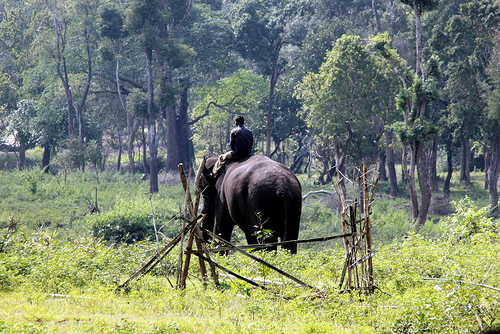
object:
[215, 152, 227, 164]
knee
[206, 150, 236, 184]
leg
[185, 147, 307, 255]
elephant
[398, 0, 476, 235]
trees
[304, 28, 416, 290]
trees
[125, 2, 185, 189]
trees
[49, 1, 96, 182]
trees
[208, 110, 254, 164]
person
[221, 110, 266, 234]
man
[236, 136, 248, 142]
back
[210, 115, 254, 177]
person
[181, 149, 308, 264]
elephant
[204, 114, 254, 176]
person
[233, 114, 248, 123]
head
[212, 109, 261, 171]
man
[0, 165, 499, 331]
weeds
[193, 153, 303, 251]
elephant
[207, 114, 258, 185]
person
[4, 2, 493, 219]
forest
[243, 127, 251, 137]
shoulder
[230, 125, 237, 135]
shoulder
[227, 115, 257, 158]
man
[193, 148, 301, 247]
animal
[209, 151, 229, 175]
pants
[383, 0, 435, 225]
tree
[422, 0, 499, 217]
tree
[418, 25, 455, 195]
tree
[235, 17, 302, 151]
tree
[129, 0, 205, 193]
tree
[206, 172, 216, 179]
foot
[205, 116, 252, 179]
man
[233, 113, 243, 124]
hair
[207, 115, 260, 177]
person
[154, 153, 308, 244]
elephant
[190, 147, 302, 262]
arm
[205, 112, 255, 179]
man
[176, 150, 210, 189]
ear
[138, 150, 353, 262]
elephant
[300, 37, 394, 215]
tree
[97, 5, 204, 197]
tree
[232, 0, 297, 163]
tree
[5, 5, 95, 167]
tree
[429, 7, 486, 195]
tree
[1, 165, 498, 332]
field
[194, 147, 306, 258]
elephant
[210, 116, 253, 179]
man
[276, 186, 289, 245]
tail